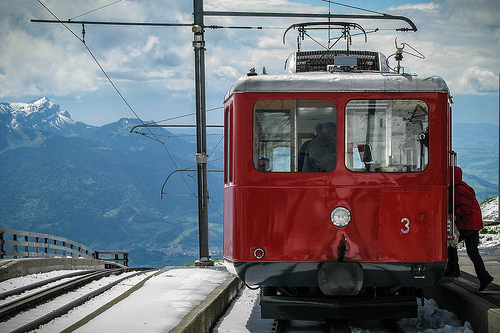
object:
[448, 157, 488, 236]
elephant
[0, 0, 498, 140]
sky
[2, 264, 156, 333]
tracks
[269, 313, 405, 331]
tracks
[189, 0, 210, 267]
power line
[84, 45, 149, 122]
line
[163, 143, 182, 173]
line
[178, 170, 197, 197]
line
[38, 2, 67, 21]
line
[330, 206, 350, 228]
light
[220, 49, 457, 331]
red train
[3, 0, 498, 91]
clouds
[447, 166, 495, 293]
child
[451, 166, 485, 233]
shirt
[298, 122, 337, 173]
passenger